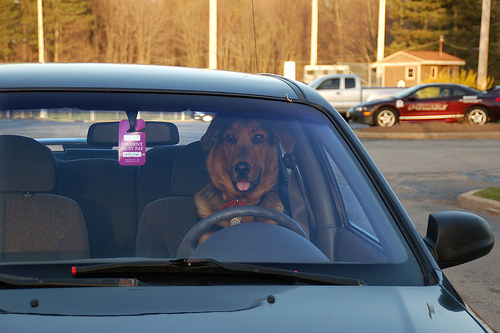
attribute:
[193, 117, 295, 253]
dog — large, sitting, black, brown, beige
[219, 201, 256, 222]
collar — red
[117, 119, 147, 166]
permit — hanging, purple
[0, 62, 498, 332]
car — dark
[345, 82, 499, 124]
car — far away, parked, red, compact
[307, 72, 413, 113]
truck — silver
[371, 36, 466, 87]
house — small, white, brown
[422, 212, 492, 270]
mirror — black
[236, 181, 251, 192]
toungue — pink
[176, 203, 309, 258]
steering wheel — grey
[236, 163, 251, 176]
nose — black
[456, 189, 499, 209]
curb — concrete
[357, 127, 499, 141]
curb — concrete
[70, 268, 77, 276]
tip — red